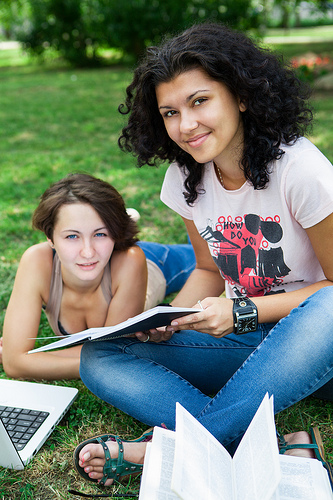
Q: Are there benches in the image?
A: No, there are no benches.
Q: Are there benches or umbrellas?
A: No, there are no benches or umbrellas.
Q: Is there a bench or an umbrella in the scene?
A: No, there are no benches or umbrellas.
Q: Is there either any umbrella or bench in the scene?
A: No, there are no benches or umbrellas.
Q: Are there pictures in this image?
A: No, there are no pictures.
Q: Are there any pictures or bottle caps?
A: No, there are no pictures or bottle caps.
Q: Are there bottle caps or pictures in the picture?
A: No, there are no pictures or bottle caps.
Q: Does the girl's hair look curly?
A: Yes, the hair is curly.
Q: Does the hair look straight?
A: No, the hair is curly.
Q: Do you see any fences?
A: No, there are no fences.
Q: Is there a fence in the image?
A: No, there are no fences.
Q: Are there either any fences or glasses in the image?
A: No, there are no fences or glasses.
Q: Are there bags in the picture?
A: No, there are no bags.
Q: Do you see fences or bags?
A: No, there are no bags or fences.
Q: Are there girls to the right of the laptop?
A: Yes, there is a girl to the right of the laptop.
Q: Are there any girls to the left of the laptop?
A: No, the girl is to the right of the laptop.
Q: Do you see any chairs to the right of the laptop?
A: No, there is a girl to the right of the laptop.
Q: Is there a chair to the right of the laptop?
A: No, there is a girl to the right of the laptop.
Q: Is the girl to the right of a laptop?
A: Yes, the girl is to the right of a laptop.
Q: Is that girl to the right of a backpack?
A: No, the girl is to the right of a laptop.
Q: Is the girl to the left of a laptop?
A: No, the girl is to the right of a laptop.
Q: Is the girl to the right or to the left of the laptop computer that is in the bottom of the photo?
A: The girl is to the right of the laptop.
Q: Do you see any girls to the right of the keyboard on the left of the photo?
A: Yes, there is a girl to the right of the keyboard.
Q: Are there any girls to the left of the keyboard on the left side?
A: No, the girl is to the right of the keyboard.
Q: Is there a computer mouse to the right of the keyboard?
A: No, there is a girl to the right of the keyboard.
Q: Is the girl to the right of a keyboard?
A: Yes, the girl is to the right of a keyboard.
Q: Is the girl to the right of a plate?
A: No, the girl is to the right of a keyboard.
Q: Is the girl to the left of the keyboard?
A: No, the girl is to the right of the keyboard.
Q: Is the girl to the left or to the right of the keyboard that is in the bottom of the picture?
A: The girl is to the right of the keyboard.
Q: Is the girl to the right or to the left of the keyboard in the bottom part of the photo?
A: The girl is to the right of the keyboard.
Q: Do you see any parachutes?
A: No, there are no parachutes.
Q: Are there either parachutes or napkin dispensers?
A: No, there are no parachutes or napkin dispensers.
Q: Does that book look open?
A: Yes, the book is open.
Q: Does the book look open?
A: Yes, the book is open.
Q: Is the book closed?
A: No, the book is open.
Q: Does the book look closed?
A: No, the book is open.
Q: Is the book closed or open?
A: The book is open.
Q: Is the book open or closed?
A: The book is open.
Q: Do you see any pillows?
A: No, there are no pillows.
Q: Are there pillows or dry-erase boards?
A: No, there are no pillows or dry-erase boards.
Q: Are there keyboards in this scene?
A: Yes, there is a keyboard.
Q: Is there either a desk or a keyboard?
A: Yes, there is a keyboard.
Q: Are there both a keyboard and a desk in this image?
A: No, there is a keyboard but no desks.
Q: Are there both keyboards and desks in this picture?
A: No, there is a keyboard but no desks.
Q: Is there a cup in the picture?
A: No, there are no cups.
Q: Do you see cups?
A: No, there are no cups.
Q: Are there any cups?
A: No, there are no cups.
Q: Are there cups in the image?
A: No, there are no cups.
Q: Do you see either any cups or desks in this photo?
A: No, there are no cups or desks.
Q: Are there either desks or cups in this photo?
A: No, there are no cups or desks.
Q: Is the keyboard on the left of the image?
A: Yes, the keyboard is on the left of the image.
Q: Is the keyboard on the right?
A: No, the keyboard is on the left of the image.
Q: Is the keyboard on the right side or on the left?
A: The keyboard is on the left of the image.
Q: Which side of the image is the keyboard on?
A: The keyboard is on the left of the image.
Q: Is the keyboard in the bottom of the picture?
A: Yes, the keyboard is in the bottom of the image.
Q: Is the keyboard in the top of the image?
A: No, the keyboard is in the bottom of the image.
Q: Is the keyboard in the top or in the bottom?
A: The keyboard is in the bottom of the image.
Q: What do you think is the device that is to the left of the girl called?
A: The device is a keyboard.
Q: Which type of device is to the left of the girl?
A: The device is a keyboard.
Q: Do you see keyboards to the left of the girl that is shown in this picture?
A: Yes, there is a keyboard to the left of the girl.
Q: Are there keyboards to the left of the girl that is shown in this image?
A: Yes, there is a keyboard to the left of the girl.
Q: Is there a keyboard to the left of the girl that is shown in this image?
A: Yes, there is a keyboard to the left of the girl.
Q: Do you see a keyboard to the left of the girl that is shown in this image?
A: Yes, there is a keyboard to the left of the girl.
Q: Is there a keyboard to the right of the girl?
A: No, the keyboard is to the left of the girl.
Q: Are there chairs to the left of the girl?
A: No, there is a keyboard to the left of the girl.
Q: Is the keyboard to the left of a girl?
A: Yes, the keyboard is to the left of a girl.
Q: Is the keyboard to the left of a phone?
A: No, the keyboard is to the left of a girl.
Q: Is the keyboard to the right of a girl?
A: No, the keyboard is to the left of a girl.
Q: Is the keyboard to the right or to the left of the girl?
A: The keyboard is to the left of the girl.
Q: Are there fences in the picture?
A: No, there are no fences.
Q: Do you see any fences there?
A: No, there are no fences.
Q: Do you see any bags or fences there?
A: No, there are no fences or bags.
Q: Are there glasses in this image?
A: No, there are no glasses.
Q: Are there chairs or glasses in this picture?
A: No, there are no glasses or chairs.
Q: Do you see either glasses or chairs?
A: No, there are no glasses or chairs.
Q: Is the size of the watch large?
A: Yes, the watch is large.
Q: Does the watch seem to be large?
A: Yes, the watch is large.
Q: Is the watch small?
A: No, the watch is large.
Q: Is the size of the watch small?
A: No, the watch is large.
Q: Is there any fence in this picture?
A: No, there are no fences.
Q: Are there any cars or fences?
A: No, there are no fences or cars.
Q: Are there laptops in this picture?
A: Yes, there is a laptop.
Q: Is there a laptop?
A: Yes, there is a laptop.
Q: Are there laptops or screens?
A: Yes, there is a laptop.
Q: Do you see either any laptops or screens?
A: Yes, there is a laptop.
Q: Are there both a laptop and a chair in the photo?
A: No, there is a laptop but no chairs.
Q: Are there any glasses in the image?
A: No, there are no glasses.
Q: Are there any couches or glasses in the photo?
A: No, there are no glasses or couches.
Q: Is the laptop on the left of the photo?
A: Yes, the laptop is on the left of the image.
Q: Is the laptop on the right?
A: No, the laptop is on the left of the image.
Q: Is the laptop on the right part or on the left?
A: The laptop is on the left of the image.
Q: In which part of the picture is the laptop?
A: The laptop is on the left of the image.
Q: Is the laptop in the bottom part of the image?
A: Yes, the laptop is in the bottom of the image.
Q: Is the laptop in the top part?
A: No, the laptop is in the bottom of the image.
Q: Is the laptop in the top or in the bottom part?
A: The laptop is in the bottom of the image.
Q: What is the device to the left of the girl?
A: The device is a laptop.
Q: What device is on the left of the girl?
A: The device is a laptop.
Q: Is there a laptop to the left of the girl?
A: Yes, there is a laptop to the left of the girl.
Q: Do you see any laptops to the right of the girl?
A: No, the laptop is to the left of the girl.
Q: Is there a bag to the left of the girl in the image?
A: No, there is a laptop to the left of the girl.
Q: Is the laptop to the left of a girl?
A: Yes, the laptop is to the left of a girl.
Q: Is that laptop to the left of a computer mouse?
A: No, the laptop is to the left of a girl.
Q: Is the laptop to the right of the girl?
A: No, the laptop is to the left of the girl.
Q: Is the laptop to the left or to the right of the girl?
A: The laptop is to the left of the girl.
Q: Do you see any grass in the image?
A: Yes, there is grass.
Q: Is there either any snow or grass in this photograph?
A: Yes, there is grass.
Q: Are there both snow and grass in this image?
A: No, there is grass but no snow.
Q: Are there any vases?
A: No, there are no vases.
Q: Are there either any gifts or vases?
A: No, there are no vases or gifts.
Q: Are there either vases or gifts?
A: No, there are no vases or gifts.